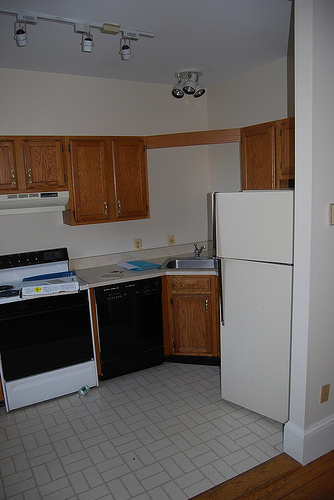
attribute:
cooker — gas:
[1, 245, 99, 413]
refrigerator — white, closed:
[204, 184, 297, 434]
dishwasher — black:
[92, 273, 165, 378]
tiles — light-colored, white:
[0, 360, 284, 499]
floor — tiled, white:
[0, 360, 334, 499]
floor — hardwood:
[189, 449, 333, 498]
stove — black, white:
[0, 247, 91, 305]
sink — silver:
[157, 256, 217, 271]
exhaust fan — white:
[0, 189, 68, 216]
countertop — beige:
[67, 239, 213, 288]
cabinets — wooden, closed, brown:
[2, 117, 295, 227]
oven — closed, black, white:
[0, 284, 100, 414]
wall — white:
[0, 65, 213, 262]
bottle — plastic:
[74, 384, 91, 401]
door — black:
[0, 290, 95, 382]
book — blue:
[126, 258, 162, 272]